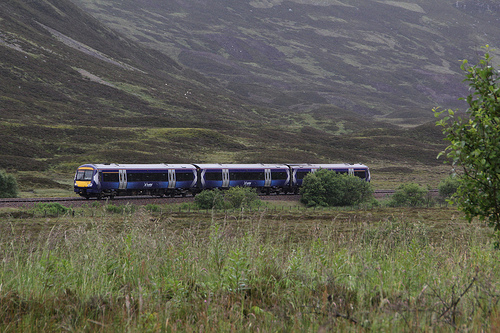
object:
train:
[73, 163, 371, 199]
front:
[74, 164, 98, 194]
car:
[193, 162, 290, 195]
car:
[286, 163, 372, 197]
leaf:
[447, 106, 458, 118]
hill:
[0, 1, 500, 184]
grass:
[2, 201, 498, 333]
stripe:
[100, 179, 304, 189]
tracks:
[0, 183, 481, 204]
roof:
[89, 163, 367, 170]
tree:
[430, 42, 499, 232]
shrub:
[288, 169, 443, 208]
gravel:
[1, 189, 444, 211]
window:
[76, 170, 93, 181]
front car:
[73, 163, 199, 199]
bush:
[204, 167, 462, 208]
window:
[103, 173, 119, 183]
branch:
[451, 275, 475, 301]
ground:
[0, 195, 500, 332]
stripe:
[78, 166, 94, 170]